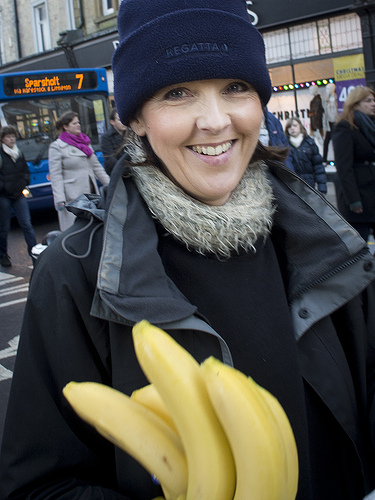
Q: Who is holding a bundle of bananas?
A: The woman.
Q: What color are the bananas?
A: Yellow.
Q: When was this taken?
A: During the day.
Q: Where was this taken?
A: On a street.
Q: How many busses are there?
A: One.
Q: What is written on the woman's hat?
A: Regatta.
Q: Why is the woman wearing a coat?
A: It is cold.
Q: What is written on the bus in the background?
A: Sparsholt.